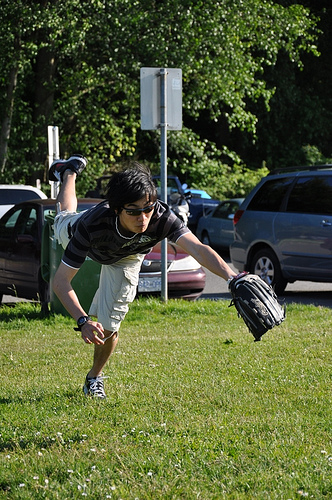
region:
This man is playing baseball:
[56, 159, 172, 301]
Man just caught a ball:
[41, 170, 204, 402]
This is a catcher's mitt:
[227, 268, 286, 343]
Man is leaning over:
[27, 138, 193, 304]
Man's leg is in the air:
[38, 142, 92, 244]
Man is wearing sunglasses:
[112, 196, 161, 217]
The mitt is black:
[218, 266, 292, 341]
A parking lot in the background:
[4, 157, 318, 293]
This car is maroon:
[0, 202, 206, 314]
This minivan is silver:
[220, 159, 330, 304]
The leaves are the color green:
[55, 10, 274, 61]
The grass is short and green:
[32, 417, 262, 498]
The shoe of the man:
[69, 365, 115, 404]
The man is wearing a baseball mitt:
[225, 268, 290, 344]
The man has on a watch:
[72, 312, 94, 331]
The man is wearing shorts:
[45, 197, 146, 341]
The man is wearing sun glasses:
[118, 200, 158, 217]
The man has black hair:
[102, 162, 160, 207]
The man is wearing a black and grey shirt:
[62, 196, 191, 280]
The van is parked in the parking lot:
[224, 161, 331, 296]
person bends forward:
[35, 142, 297, 407]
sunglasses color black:
[120, 199, 159, 216]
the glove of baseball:
[219, 270, 290, 349]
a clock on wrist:
[69, 309, 90, 332]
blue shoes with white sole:
[42, 154, 91, 186]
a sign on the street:
[135, 63, 189, 141]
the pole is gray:
[151, 65, 180, 304]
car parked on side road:
[221, 152, 331, 296]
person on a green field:
[13, 153, 288, 473]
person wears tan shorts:
[36, 145, 246, 403]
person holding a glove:
[218, 271, 306, 345]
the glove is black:
[222, 254, 286, 363]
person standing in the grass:
[39, 145, 293, 436]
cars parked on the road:
[22, 148, 180, 319]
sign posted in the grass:
[125, 65, 222, 310]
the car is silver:
[213, 162, 328, 286]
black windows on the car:
[252, 165, 330, 220]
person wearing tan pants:
[41, 185, 147, 371]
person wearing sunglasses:
[84, 192, 171, 228]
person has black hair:
[96, 156, 163, 228]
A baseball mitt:
[224, 270, 287, 340]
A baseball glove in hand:
[226, 273, 283, 343]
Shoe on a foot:
[80, 369, 108, 401]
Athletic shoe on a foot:
[82, 368, 107, 400]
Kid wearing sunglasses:
[121, 202, 157, 217]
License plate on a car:
[138, 276, 165, 292]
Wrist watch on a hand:
[72, 315, 92, 329]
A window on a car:
[212, 201, 233, 217]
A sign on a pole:
[140, 67, 181, 131]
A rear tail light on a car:
[232, 208, 244, 225]